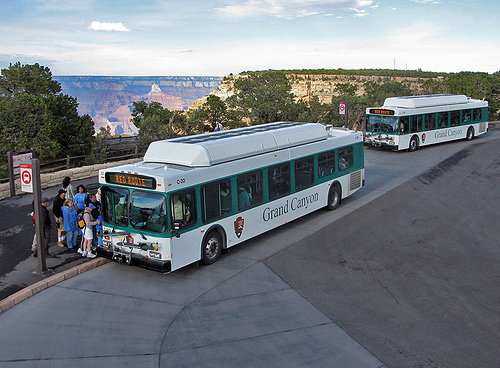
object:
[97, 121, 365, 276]
bus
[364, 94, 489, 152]
bus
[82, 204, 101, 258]
girl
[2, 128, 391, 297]
street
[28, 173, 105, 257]
people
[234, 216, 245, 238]
sign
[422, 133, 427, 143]
sign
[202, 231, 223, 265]
tire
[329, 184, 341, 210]
tire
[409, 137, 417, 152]
tire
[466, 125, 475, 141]
tire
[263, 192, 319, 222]
grand canyon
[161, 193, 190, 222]
driver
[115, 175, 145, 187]
red route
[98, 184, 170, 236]
window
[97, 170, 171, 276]
front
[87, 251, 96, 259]
shoes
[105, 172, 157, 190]
sign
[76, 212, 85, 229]
backpack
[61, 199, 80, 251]
woman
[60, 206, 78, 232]
jacket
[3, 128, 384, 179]
overlook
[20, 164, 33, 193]
sign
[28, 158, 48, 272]
signpost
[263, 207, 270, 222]
letter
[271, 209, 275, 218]
letter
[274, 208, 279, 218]
letter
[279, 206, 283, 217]
letter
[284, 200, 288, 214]
letter